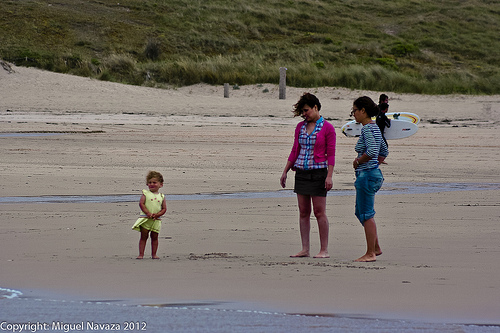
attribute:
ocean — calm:
[1, 287, 498, 332]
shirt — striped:
[352, 121, 389, 171]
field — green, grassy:
[3, 0, 498, 96]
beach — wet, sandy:
[32, 87, 487, 304]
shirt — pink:
[285, 118, 335, 165]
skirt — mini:
[288, 168, 329, 196]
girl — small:
[130, 168, 170, 262]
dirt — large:
[5, 66, 496, 131]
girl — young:
[120, 167, 185, 262]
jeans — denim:
[357, 172, 382, 218]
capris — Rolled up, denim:
[352, 165, 387, 223]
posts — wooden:
[226, 60, 301, 110]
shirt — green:
[138, 187, 165, 217]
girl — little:
[131, 170, 168, 259]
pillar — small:
[204, 71, 251, 125]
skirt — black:
[292, 170, 328, 197]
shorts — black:
[288, 165, 331, 200]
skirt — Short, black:
[290, 168, 329, 198]